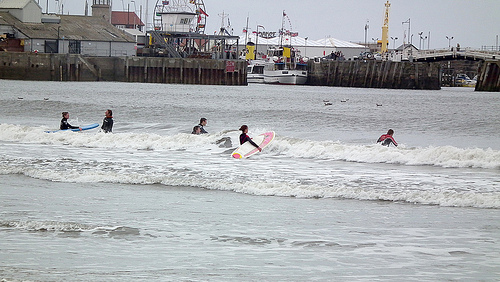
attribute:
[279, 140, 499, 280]
ocean — rippling, gray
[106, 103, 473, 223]
waves — white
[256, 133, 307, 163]
wheel — wheeled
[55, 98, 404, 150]
people — skating